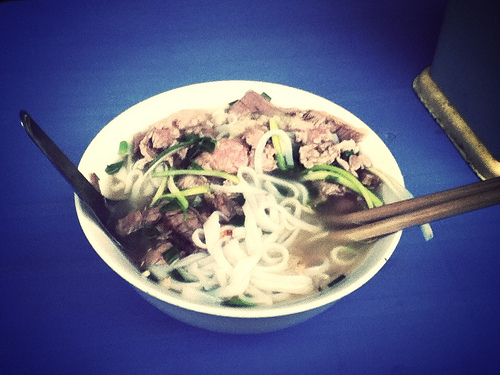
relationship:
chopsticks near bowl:
[315, 150, 500, 242] [72, 57, 409, 370]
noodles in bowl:
[108, 123, 368, 285] [72, 57, 409, 370]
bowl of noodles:
[72, 57, 409, 370] [108, 123, 368, 285]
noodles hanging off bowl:
[108, 123, 368, 285] [72, 57, 409, 370]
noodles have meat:
[108, 123, 368, 285] [142, 126, 246, 234]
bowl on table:
[72, 57, 409, 370] [1, 17, 495, 375]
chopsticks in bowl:
[315, 150, 500, 242] [72, 57, 409, 370]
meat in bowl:
[142, 126, 246, 234] [72, 57, 409, 370]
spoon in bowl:
[15, 102, 191, 277] [72, 57, 409, 370]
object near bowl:
[403, 66, 499, 173] [72, 57, 409, 370]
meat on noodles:
[142, 126, 246, 234] [108, 123, 368, 285]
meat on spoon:
[142, 126, 246, 234] [15, 102, 191, 277]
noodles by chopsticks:
[108, 123, 368, 285] [315, 150, 500, 242]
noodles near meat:
[108, 123, 368, 285] [142, 126, 246, 234]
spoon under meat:
[15, 102, 191, 277] [142, 126, 246, 234]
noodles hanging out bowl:
[108, 123, 368, 285] [72, 57, 409, 370]